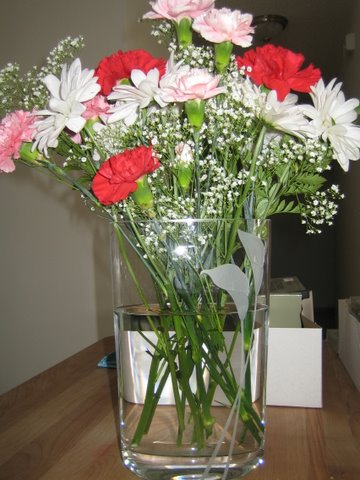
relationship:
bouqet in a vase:
[0, 0, 360, 448] [110, 218, 272, 479]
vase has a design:
[110, 218, 272, 479] [198, 228, 265, 477]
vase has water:
[110, 218, 272, 479] [113, 303, 269, 458]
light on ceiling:
[244, 13, 288, 45] [191, 0, 357, 88]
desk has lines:
[0, 336, 360, 477] [0, 341, 124, 479]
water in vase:
[113, 303, 269, 458] [110, 218, 272, 479]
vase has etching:
[110, 218, 272, 479] [198, 228, 265, 477]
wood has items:
[0, 336, 360, 477] [109, 215, 323, 479]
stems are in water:
[18, 22, 332, 449] [113, 303, 269, 458]